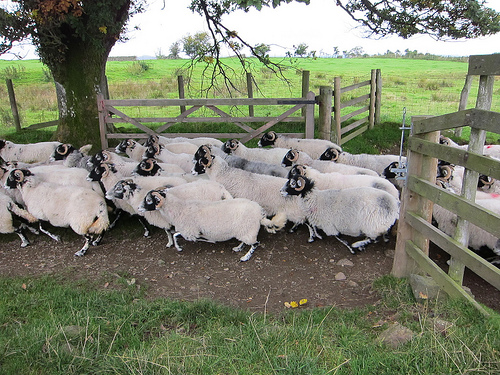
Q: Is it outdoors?
A: Yes, it is outdoors.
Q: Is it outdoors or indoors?
A: It is outdoors.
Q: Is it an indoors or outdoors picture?
A: It is outdoors.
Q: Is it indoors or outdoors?
A: It is outdoors.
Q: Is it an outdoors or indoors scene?
A: It is outdoors.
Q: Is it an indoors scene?
A: No, it is outdoors.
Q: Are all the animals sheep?
A: Yes, all the animals are sheep.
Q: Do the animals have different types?
A: No, all the animals are sheep.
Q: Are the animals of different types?
A: No, all the animals are sheep.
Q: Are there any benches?
A: No, there are no benches.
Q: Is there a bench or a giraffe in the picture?
A: No, there are no benches or giraffes.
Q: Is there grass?
A: Yes, there is grass.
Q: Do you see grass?
A: Yes, there is grass.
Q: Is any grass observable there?
A: Yes, there is grass.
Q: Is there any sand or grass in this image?
A: Yes, there is grass.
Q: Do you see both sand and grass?
A: No, there is grass but no sand.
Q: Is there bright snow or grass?
A: Yes, there is bright grass.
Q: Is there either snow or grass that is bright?
A: Yes, the grass is bright.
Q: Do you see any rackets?
A: No, there are no rackets.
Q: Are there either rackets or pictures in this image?
A: No, there are no rackets or pictures.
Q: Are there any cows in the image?
A: No, there are no cows.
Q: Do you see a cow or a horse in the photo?
A: No, there are no cows or horses.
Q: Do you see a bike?
A: No, there are no bikes.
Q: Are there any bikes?
A: No, there are no bikes.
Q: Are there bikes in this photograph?
A: No, there are no bikes.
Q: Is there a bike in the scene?
A: No, there are no bikes.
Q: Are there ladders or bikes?
A: No, there are no bikes or ladders.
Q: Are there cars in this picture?
A: No, there are no cars.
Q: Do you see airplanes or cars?
A: No, there are no cars or airplanes.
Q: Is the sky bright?
A: Yes, the sky is bright.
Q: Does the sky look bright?
A: Yes, the sky is bright.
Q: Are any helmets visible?
A: No, there are no helmets.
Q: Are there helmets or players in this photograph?
A: No, there are no helmets or players.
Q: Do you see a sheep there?
A: Yes, there is a sheep.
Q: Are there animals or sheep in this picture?
A: Yes, there is a sheep.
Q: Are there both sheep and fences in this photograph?
A: Yes, there are both a sheep and a fence.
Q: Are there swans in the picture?
A: No, there are no swans.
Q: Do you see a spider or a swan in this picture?
A: No, there are no swans or spiders.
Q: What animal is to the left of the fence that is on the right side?
A: The animal is a sheep.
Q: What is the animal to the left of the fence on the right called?
A: The animal is a sheep.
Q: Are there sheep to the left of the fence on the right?
A: Yes, there is a sheep to the left of the fence.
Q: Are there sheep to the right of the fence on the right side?
A: No, the sheep is to the left of the fence.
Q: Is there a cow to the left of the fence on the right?
A: No, there is a sheep to the left of the fence.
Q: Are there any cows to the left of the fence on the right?
A: No, there is a sheep to the left of the fence.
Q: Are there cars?
A: No, there are no cars.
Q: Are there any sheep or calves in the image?
A: Yes, there is a sheep.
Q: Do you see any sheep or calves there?
A: Yes, there is a sheep.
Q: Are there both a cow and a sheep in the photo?
A: No, there is a sheep but no cows.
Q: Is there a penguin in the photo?
A: No, there are no penguins.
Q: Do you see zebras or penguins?
A: No, there are no penguins or zebras.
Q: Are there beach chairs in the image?
A: No, there are no beach chairs.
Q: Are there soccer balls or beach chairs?
A: No, there are no beach chairs or soccer balls.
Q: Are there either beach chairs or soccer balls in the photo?
A: No, there are no beach chairs or soccer balls.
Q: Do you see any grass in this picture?
A: Yes, there is grass.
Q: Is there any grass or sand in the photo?
A: Yes, there is grass.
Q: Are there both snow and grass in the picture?
A: No, there is grass but no snow.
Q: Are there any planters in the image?
A: No, there are no planters.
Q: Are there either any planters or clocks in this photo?
A: No, there are no planters or clocks.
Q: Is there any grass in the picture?
A: Yes, there is grass.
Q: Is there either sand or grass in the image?
A: Yes, there is grass.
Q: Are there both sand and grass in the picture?
A: No, there is grass but no sand.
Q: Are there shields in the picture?
A: No, there are no shields.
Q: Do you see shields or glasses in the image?
A: No, there are no shields or glasses.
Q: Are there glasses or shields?
A: No, there are no shields or glasses.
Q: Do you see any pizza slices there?
A: No, there are no pizza slices.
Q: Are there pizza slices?
A: No, there are no pizza slices.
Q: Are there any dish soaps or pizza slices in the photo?
A: No, there are no pizza slices or dish soaps.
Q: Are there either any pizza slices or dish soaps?
A: No, there are no pizza slices or dish soaps.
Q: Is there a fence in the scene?
A: Yes, there is a fence.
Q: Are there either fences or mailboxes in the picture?
A: Yes, there is a fence.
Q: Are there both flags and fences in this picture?
A: No, there is a fence but no flags.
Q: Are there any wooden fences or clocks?
A: Yes, there is a wood fence.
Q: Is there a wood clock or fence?
A: Yes, there is a wood fence.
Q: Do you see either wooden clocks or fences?
A: Yes, there is a wood fence.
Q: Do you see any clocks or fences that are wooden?
A: Yes, the fence is wooden.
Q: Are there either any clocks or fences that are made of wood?
A: Yes, the fence is made of wood.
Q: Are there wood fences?
A: Yes, there is a fence that is made of wood.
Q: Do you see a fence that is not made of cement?
A: Yes, there is a fence that is made of wood.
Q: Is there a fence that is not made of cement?
A: Yes, there is a fence that is made of wood.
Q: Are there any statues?
A: No, there are no statues.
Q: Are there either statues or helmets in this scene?
A: No, there are no statues or helmets.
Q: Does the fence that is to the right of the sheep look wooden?
A: Yes, the fence is wooden.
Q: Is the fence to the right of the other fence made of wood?
A: Yes, the fence is made of wood.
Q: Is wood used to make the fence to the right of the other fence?
A: Yes, the fence is made of wood.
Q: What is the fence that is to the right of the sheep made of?
A: The fence is made of wood.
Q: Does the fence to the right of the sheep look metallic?
A: No, the fence is wooden.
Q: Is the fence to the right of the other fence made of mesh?
A: No, the fence is made of wood.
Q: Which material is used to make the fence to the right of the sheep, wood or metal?
A: The fence is made of wood.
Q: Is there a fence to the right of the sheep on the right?
A: Yes, there is a fence to the right of the sheep.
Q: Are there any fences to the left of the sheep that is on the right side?
A: No, the fence is to the right of the sheep.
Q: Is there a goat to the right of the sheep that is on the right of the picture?
A: No, there is a fence to the right of the sheep.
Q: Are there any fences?
A: Yes, there is a fence.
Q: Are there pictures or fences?
A: Yes, there is a fence.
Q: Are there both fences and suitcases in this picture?
A: No, there is a fence but no suitcases.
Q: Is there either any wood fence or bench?
A: Yes, there is a wood fence.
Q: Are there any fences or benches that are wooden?
A: Yes, the fence is wooden.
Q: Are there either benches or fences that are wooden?
A: Yes, the fence is wooden.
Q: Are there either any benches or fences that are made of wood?
A: Yes, the fence is made of wood.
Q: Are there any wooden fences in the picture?
A: Yes, there is a wood fence.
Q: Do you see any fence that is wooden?
A: Yes, there is a wood fence.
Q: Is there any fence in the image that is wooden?
A: Yes, there is a fence that is wooden.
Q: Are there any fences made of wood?
A: Yes, there is a fence that is made of wood.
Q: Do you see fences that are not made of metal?
A: Yes, there is a fence that is made of wood.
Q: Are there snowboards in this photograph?
A: No, there are no snowboards.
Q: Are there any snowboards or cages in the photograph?
A: No, there are no snowboards or cages.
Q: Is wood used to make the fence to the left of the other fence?
A: Yes, the fence is made of wood.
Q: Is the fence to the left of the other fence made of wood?
A: Yes, the fence is made of wood.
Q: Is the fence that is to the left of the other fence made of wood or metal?
A: The fence is made of wood.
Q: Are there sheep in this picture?
A: Yes, there is a sheep.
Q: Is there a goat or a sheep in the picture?
A: Yes, there is a sheep.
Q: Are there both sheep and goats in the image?
A: No, there is a sheep but no goats.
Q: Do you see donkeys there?
A: No, there are no donkeys.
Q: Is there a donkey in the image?
A: No, there are no donkeys.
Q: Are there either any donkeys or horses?
A: No, there are no donkeys or horses.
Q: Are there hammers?
A: No, there are no hammers.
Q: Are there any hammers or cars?
A: No, there are no hammers or cars.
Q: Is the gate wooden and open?
A: Yes, the gate is wooden and open.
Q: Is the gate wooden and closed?
A: No, the gate is wooden but open.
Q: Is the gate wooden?
A: Yes, the gate is wooden.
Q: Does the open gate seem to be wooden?
A: Yes, the gate is wooden.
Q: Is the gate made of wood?
A: Yes, the gate is made of wood.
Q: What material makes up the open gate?
A: The gate is made of wood.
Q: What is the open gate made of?
A: The gate is made of wood.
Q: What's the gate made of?
A: The gate is made of wood.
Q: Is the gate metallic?
A: No, the gate is wooden.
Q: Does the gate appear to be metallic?
A: No, the gate is wooden.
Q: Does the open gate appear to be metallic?
A: No, the gate is wooden.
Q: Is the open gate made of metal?
A: No, the gate is made of wood.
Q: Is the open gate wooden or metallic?
A: The gate is wooden.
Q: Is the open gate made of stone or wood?
A: The gate is made of wood.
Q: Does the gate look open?
A: Yes, the gate is open.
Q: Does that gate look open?
A: Yes, the gate is open.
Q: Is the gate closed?
A: No, the gate is open.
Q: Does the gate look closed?
A: No, the gate is open.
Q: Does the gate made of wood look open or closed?
A: The gate is open.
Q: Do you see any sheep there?
A: Yes, there is a sheep.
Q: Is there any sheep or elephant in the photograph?
A: Yes, there is a sheep.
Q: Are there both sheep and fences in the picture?
A: Yes, there are both a sheep and a fence.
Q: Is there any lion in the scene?
A: No, there are no lions.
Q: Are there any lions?
A: No, there are no lions.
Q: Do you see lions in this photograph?
A: No, there are no lions.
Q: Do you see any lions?
A: No, there are no lions.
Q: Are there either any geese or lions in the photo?
A: No, there are no lions or geese.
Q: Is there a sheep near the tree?
A: Yes, there is a sheep near the tree.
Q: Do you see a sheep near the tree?
A: Yes, there is a sheep near the tree.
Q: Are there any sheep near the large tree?
A: Yes, there is a sheep near the tree.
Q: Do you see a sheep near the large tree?
A: Yes, there is a sheep near the tree.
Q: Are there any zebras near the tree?
A: No, there is a sheep near the tree.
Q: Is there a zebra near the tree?
A: No, there is a sheep near the tree.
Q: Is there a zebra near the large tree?
A: No, there is a sheep near the tree.